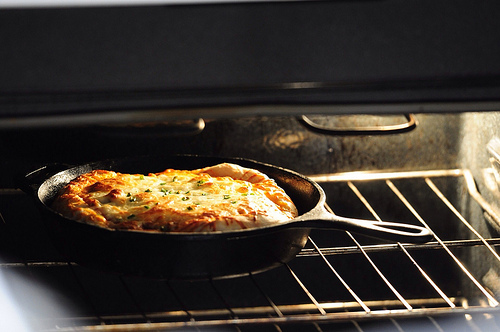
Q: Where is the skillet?
A: In the oven.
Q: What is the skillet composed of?
A: Iron.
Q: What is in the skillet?
A: Bread.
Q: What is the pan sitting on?
A: An oven rack.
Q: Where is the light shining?
A: In the oven.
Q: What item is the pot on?
A: A wire rack.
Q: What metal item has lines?
A: A rack.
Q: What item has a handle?
A: A pot.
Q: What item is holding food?
A: A pot.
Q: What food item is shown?
A: Pizza.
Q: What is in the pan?
A: A pizza.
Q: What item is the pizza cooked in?
A: The stove.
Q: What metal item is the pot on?
A: A rack.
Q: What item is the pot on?
A: A rack.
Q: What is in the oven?
A: Food.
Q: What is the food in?
A: A pan.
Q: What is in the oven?
A: Food.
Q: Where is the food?
A: In oven.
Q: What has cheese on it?
A: The food.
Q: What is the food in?
A: The oven.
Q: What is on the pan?
A: Handle.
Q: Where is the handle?
A: On the pan.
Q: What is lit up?
A: The oven.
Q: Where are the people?
A: None in photo.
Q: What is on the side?
A: Grooves where you can adjust the oven racks.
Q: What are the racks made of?
A: Steel.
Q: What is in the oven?
A: Skillet.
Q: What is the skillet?
A: Iron.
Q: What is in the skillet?
A: Pizza.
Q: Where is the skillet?
A: In the oven.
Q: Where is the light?
A: Inside the oven.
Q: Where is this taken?
A: Kitchen.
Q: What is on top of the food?
A: Cheese.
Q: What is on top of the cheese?
A: Green garnish.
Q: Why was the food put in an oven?
A: To cook.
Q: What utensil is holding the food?
A: A pan.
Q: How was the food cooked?
A: It was baked.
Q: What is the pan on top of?
A: An oven rack.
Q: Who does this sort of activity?
A: A cook.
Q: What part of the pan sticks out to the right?
A: The handle.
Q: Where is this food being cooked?
A: In an oven.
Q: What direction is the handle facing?
A: To the right.